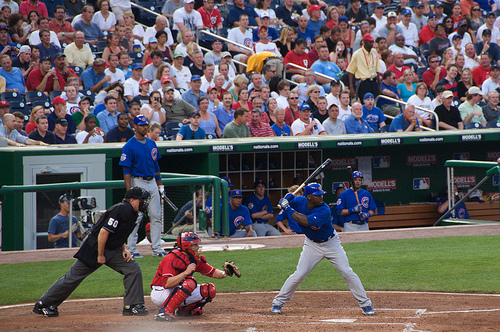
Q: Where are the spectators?
A: In the stands.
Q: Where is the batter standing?
A: To the left of home plate.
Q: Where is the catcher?
A: Behind the batter.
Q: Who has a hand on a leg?
A: The umpire.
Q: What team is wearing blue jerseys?
A: The Cubs.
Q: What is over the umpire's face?
A: A protective mask.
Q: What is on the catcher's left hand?
A: A baseball mitt.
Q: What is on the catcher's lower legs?
A: Shin pads.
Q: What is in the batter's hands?
A: A bat.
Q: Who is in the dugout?
A: Numerous baseball players.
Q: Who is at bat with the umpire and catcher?
A: A baseball player.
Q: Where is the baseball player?
A: At bat.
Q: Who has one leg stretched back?
A: The umpire.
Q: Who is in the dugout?
A: Cubs players.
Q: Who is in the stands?
A: Baseball fans.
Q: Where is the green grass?
A: On the field.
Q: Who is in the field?
A: Baseball players.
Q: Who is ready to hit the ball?
A: The batter.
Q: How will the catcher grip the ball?
A: Mitt.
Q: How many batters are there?
A: One.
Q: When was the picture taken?
A: Daytime.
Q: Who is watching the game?
A: Spectators.